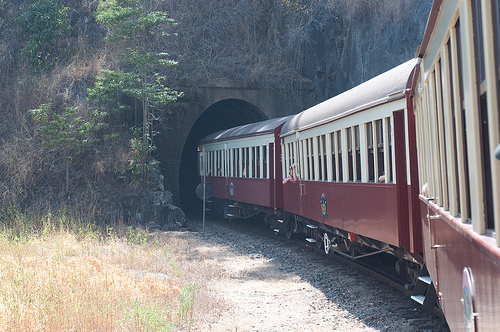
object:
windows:
[266, 144, 273, 181]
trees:
[93, 0, 184, 165]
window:
[323, 132, 343, 179]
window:
[343, 124, 357, 178]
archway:
[152, 87, 284, 216]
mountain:
[0, 0, 430, 234]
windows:
[285, 139, 317, 182]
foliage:
[18, 0, 182, 174]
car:
[195, 0, 498, 332]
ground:
[0, 220, 440, 332]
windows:
[213, 142, 238, 180]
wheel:
[285, 225, 299, 239]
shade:
[188, 218, 450, 332]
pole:
[203, 152, 207, 233]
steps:
[411, 264, 437, 309]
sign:
[320, 193, 328, 217]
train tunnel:
[178, 98, 270, 221]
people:
[282, 164, 299, 185]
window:
[471, 3, 494, 231]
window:
[453, 17, 468, 234]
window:
[331, 127, 343, 182]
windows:
[403, 35, 498, 205]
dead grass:
[0, 227, 183, 331]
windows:
[337, 119, 365, 191]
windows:
[228, 147, 268, 176]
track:
[209, 214, 445, 313]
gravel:
[189, 221, 434, 332]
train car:
[201, 122, 296, 225]